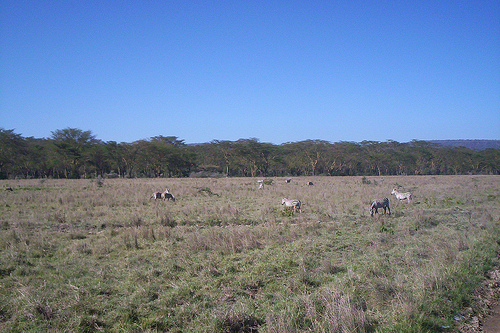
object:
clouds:
[0, 0, 499, 147]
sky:
[0, 0, 499, 146]